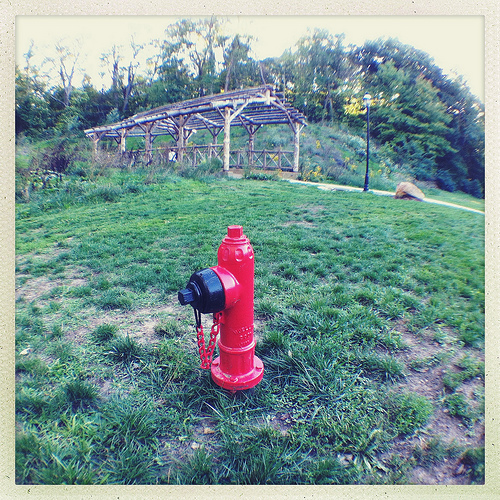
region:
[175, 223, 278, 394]
a red and black fire hydrent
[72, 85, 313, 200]
a wooden archway over creek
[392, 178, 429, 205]
a large rock placed along the pathway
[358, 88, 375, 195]
a lamp post along a pathway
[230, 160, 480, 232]
a walking pathway from a bridge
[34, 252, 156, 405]
spots of grass and dirt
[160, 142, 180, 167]
a person walking on the wooden bridge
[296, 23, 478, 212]
tall trees complete the surroundings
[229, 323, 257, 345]
company name imprinted on a red fire hydrent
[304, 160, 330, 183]
yellow flowering bush on the side of a path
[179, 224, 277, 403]
Red and black fire hydrant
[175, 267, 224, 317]
Black cap on the fire hydrant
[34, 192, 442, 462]
Green field with a fire hydrant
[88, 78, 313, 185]
Wood bridge along the sidewalk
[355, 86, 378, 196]
Street light along the sidewalk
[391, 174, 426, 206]
Bornw and grey boulder next to the sidewalk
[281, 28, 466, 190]
Green trees in teh background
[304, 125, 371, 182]
Hill with yellow flowers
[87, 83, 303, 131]
Roof of the wooden bridge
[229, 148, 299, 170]
Side rail of the wooden bridge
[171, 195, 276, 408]
this is a hydrant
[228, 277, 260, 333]
the hydrant is red in color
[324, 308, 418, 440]
this is a grass area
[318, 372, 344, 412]
the grass is green in color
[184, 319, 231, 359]
this is a chain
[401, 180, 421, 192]
this is a rock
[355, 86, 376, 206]
this is a pole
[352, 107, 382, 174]
the pole is black in color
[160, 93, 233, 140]
this is a structure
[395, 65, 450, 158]
this is a tree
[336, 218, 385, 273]
part of a ground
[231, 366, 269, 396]
base of a tank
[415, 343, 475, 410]
part of a ground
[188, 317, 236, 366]
part of a chain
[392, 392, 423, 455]
part of a ground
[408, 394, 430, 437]
part of a ground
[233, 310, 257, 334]
part of a tank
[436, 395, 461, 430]
part of a ground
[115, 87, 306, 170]
this is a house being built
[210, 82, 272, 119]
the roof is made of wood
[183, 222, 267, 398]
this is a hydrant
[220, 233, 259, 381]
the hydrant is red in color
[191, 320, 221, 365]
the hydrant has chains on it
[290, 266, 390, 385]
the grass are green in color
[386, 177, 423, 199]
this is a rock in front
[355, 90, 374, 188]
this is a pole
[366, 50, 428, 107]
the trees are leafy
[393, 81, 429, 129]
the leaves are green in color